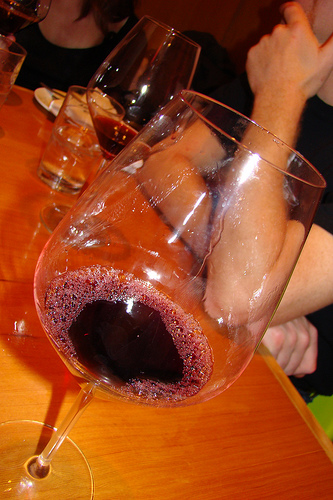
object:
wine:
[41, 262, 213, 410]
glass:
[0, 79, 329, 500]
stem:
[34, 382, 100, 476]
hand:
[242, 0, 324, 101]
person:
[141, 0, 333, 393]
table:
[0, 76, 331, 500]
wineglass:
[41, 10, 203, 263]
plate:
[31, 81, 117, 137]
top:
[0, 0, 149, 97]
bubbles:
[165, 387, 177, 399]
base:
[0, 414, 95, 500]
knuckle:
[281, 2, 302, 19]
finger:
[279, 0, 307, 27]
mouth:
[174, 86, 326, 191]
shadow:
[6, 268, 86, 408]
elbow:
[202, 234, 256, 334]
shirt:
[206, 81, 333, 388]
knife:
[39, 77, 68, 99]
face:
[298, 0, 330, 56]